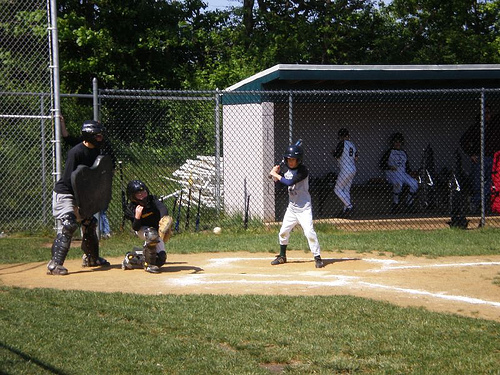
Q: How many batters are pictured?
A: One.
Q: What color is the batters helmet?
A: Dark blue.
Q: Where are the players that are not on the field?
A: Dugout.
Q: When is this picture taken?
A: During a game.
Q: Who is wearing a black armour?
A: Umpire.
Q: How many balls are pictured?
A: One.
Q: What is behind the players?
A: Silver fence.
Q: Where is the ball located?
A: In air.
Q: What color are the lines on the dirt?
A: White.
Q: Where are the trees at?
A: Behind the fence.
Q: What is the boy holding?
A: Bat.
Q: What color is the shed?
A: White.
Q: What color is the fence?
A: Silver.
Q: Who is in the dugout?
A: Baseball players.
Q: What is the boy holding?
A: Bat.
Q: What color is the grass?
A: Green.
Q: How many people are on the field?
A: Three.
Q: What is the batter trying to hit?
A: Ball.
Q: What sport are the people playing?
A: Baseball.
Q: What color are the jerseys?
A: White and blue.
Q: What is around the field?
A: A chain link fence.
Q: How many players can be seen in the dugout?
A: Two.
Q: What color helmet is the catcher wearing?
A: Black.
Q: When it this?
A: Daytime.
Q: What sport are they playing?
A: Baseball.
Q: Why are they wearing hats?
A: Protection.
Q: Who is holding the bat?
A: Batter.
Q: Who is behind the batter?
A: Catcher.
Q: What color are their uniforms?
A: White.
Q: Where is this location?
A: Baseball field.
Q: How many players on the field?
A: Three.